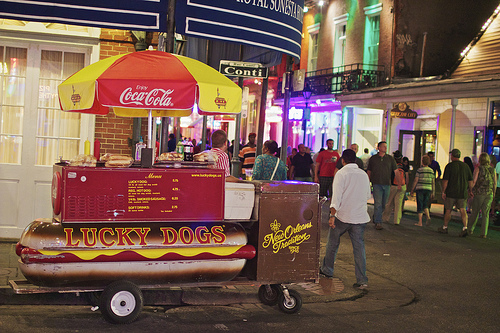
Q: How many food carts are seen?
A: One.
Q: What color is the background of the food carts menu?
A: Red.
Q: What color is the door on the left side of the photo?
A: White.